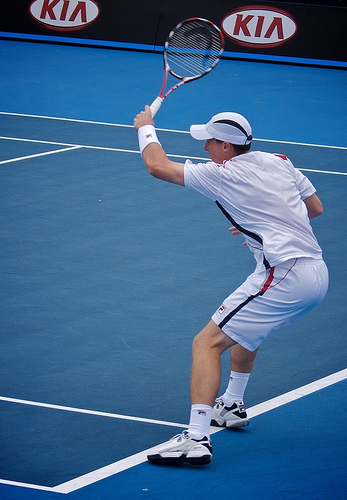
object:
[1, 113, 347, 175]
boundary line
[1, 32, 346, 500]
court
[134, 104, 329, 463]
man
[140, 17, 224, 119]
racket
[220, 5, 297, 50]
advertisement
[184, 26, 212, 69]
logo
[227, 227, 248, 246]
right hand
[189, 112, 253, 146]
cap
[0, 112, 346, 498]
playable area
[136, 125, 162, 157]
wristband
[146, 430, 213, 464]
shoe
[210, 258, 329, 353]
shorts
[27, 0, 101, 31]
logo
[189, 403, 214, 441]
sock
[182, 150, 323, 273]
shirt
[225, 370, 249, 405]
sock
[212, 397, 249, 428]
shoe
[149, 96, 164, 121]
white handle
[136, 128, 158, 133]
wrist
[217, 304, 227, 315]
logo